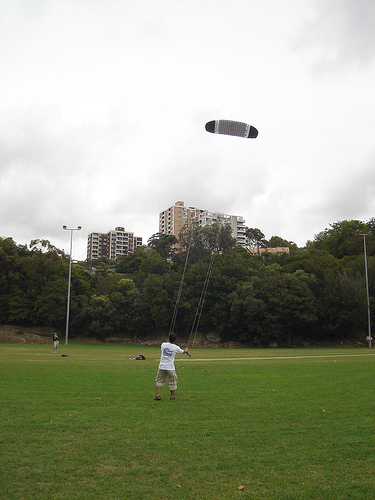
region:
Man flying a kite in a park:
[153, 116, 260, 399]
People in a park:
[49, 329, 192, 401]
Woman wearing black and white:
[49, 330, 60, 353]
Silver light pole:
[61, 221, 82, 345]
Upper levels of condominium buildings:
[86, 198, 247, 254]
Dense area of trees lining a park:
[0, 216, 373, 344]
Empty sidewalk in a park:
[158, 351, 373, 363]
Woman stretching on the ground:
[125, 353, 148, 362]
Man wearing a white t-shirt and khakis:
[151, 332, 187, 400]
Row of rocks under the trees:
[129, 337, 241, 348]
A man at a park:
[121, 284, 245, 408]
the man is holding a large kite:
[158, 114, 215, 371]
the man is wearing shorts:
[153, 369, 182, 387]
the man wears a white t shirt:
[157, 340, 182, 367]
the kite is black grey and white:
[206, 120, 259, 135]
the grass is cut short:
[78, 413, 160, 452]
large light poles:
[62, 227, 82, 349]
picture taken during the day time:
[22, 220, 110, 232]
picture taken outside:
[6, 209, 369, 493]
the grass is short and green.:
[236, 384, 288, 433]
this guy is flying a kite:
[173, 118, 257, 359]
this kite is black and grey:
[181, 112, 265, 184]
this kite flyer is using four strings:
[152, 134, 235, 363]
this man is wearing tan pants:
[147, 333, 201, 404]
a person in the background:
[41, 330, 80, 350]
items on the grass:
[52, 351, 149, 367]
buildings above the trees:
[74, 211, 276, 282]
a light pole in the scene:
[61, 219, 80, 343]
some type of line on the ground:
[168, 337, 369, 371]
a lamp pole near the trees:
[346, 219, 371, 349]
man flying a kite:
[151, 116, 260, 403]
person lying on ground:
[125, 351, 147, 363]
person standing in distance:
[50, 329, 60, 354]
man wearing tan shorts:
[152, 331, 189, 402]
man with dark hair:
[152, 330, 188, 403]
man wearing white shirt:
[151, 330, 189, 402]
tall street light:
[60, 222, 85, 346]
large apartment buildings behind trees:
[83, 197, 248, 261]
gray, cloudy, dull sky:
[0, 0, 372, 255]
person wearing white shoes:
[49, 330, 62, 355]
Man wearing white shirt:
[158, 331, 183, 372]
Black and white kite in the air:
[204, 116, 260, 141]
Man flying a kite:
[153, 329, 192, 403]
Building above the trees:
[85, 225, 144, 263]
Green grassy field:
[231, 411, 337, 480]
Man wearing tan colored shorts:
[154, 331, 179, 399]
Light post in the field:
[60, 224, 84, 345]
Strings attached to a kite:
[165, 237, 219, 345]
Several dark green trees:
[83, 264, 162, 343]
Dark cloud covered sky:
[295, 105, 360, 191]